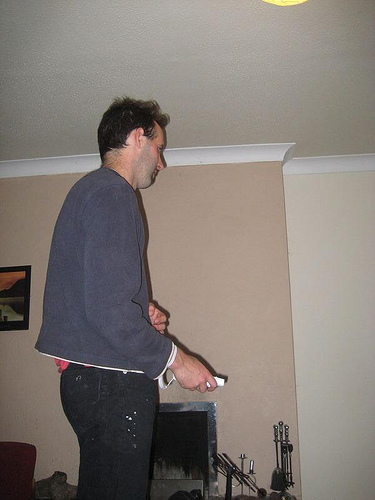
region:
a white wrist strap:
[152, 340, 188, 393]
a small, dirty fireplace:
[87, 390, 233, 493]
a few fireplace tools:
[259, 408, 305, 494]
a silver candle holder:
[220, 440, 275, 489]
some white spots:
[113, 399, 153, 452]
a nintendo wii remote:
[169, 351, 232, 400]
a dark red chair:
[2, 434, 50, 496]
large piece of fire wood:
[27, 461, 91, 498]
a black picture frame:
[0, 256, 60, 348]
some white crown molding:
[192, 133, 310, 176]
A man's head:
[68, 84, 185, 197]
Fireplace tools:
[265, 411, 309, 491]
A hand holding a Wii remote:
[159, 329, 242, 404]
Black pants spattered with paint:
[43, 358, 169, 498]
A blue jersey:
[24, 163, 192, 385]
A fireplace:
[135, 391, 221, 498]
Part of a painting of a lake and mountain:
[1, 255, 36, 333]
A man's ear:
[132, 121, 148, 153]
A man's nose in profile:
[149, 147, 167, 172]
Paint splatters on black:
[122, 406, 149, 457]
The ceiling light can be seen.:
[223, 0, 325, 29]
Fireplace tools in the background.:
[257, 409, 317, 496]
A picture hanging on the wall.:
[0, 256, 38, 339]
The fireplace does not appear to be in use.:
[131, 397, 226, 496]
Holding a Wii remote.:
[140, 319, 251, 410]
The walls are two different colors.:
[262, 189, 358, 388]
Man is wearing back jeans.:
[40, 342, 174, 496]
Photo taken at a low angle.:
[38, 81, 220, 498]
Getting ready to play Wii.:
[53, 95, 239, 432]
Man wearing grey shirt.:
[49, 86, 239, 396]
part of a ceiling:
[244, 24, 294, 67]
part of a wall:
[248, 347, 289, 384]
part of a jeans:
[110, 439, 145, 478]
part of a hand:
[178, 355, 201, 383]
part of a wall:
[200, 398, 226, 438]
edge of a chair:
[14, 448, 35, 482]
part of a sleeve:
[123, 331, 145, 363]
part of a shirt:
[50, 354, 67, 373]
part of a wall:
[13, 387, 41, 421]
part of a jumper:
[70, 327, 114, 360]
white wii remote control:
[158, 369, 226, 388]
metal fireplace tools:
[265, 419, 296, 498]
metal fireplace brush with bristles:
[268, 422, 286, 492]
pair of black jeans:
[60, 360, 159, 499]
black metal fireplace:
[145, 402, 218, 497]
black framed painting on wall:
[0, 262, 32, 333]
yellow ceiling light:
[256, 0, 312, 9]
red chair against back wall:
[0, 437, 37, 498]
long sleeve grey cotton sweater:
[34, 166, 174, 382]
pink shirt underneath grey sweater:
[53, 354, 94, 372]